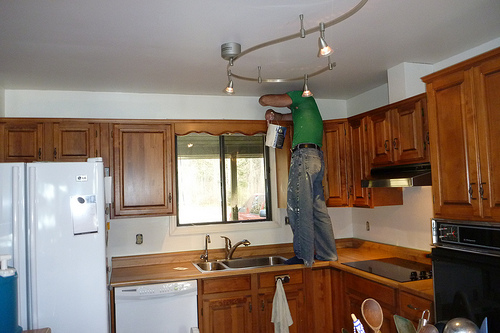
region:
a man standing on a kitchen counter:
[256, 78, 349, 270]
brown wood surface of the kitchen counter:
[121, 264, 174, 278]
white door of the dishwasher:
[103, 282, 213, 332]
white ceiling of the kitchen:
[53, 40, 148, 88]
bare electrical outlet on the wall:
[131, 229, 148, 248]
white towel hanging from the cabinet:
[272, 278, 294, 331]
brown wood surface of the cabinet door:
[120, 136, 155, 201]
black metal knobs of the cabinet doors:
[460, 180, 489, 197]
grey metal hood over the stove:
[361, 163, 434, 188]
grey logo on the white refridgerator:
[73, 172, 89, 185]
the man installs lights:
[204, 43, 351, 277]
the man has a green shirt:
[191, 36, 442, 323]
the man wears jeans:
[218, 42, 328, 273]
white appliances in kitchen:
[27, 118, 194, 299]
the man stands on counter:
[201, 25, 386, 312]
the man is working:
[214, 49, 428, 324]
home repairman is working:
[212, 35, 380, 297]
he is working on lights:
[224, 41, 398, 332]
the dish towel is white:
[261, 268, 305, 332]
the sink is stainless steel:
[188, 229, 278, 283]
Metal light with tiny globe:
[299, 74, 314, 96]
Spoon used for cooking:
[361, 295, 382, 332]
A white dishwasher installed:
[112, 279, 199, 331]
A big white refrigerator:
[0, 155, 110, 330]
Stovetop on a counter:
[341, 253, 434, 282]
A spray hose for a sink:
[201, 234, 214, 257]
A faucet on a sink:
[220, 232, 250, 260]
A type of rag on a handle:
[270, 277, 292, 332]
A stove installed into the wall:
[430, 217, 497, 330]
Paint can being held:
[265, 121, 286, 149]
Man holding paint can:
[256, 86, 340, 266]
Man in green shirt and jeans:
[252, 87, 337, 267]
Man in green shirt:
[255, 88, 340, 268]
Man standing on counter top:
[253, 88, 342, 268]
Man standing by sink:
[191, 84, 333, 273]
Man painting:
[251, 85, 340, 265]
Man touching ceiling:
[255, 86, 337, 267]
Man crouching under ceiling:
[257, 87, 340, 268]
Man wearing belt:
[256, 90, 338, 269]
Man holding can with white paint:
[258, 88, 340, 268]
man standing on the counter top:
[253, 75, 350, 270]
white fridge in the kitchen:
[0, 163, 112, 314]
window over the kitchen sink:
[169, 135, 268, 219]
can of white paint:
[262, 112, 288, 153]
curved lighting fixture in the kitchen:
[209, 11, 344, 91]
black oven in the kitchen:
[417, 220, 495, 286]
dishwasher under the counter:
[109, 283, 185, 329]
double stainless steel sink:
[204, 253, 287, 271]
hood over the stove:
[363, 165, 428, 187]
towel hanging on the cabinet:
[273, 277, 299, 330]